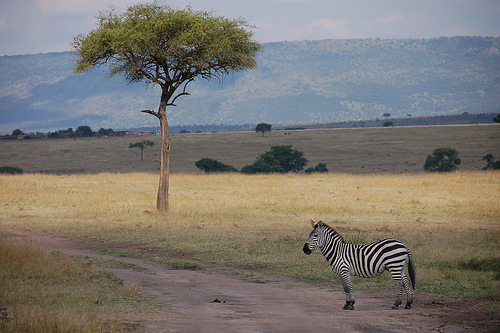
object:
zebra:
[301, 216, 419, 310]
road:
[0, 221, 500, 331]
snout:
[300, 243, 315, 256]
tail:
[403, 252, 419, 288]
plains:
[0, 122, 500, 333]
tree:
[67, 0, 263, 217]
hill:
[0, 36, 500, 139]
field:
[0, 168, 500, 332]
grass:
[0, 169, 500, 314]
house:
[96, 123, 125, 139]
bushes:
[192, 144, 329, 175]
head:
[301, 218, 333, 255]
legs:
[336, 265, 356, 311]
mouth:
[306, 242, 318, 256]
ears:
[306, 218, 317, 230]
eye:
[313, 230, 321, 240]